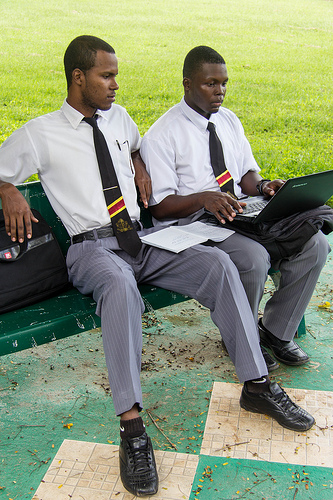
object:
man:
[139, 46, 329, 374]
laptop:
[204, 170, 333, 236]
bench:
[1, 180, 306, 358]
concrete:
[0, 232, 331, 499]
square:
[30, 437, 200, 499]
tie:
[81, 114, 144, 261]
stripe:
[106, 194, 127, 218]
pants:
[208, 227, 328, 343]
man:
[0, 35, 315, 499]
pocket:
[116, 143, 136, 179]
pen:
[114, 139, 122, 152]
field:
[0, 1, 332, 500]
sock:
[119, 417, 144, 438]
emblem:
[118, 426, 126, 432]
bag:
[0, 208, 66, 315]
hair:
[183, 45, 225, 76]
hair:
[63, 35, 116, 88]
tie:
[207, 122, 238, 200]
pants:
[64, 221, 269, 418]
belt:
[67, 218, 153, 248]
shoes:
[239, 379, 314, 432]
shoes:
[118, 434, 159, 497]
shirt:
[139, 100, 260, 226]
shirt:
[0, 100, 142, 232]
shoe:
[220, 338, 281, 371]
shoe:
[256, 316, 311, 367]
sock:
[243, 375, 272, 394]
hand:
[202, 190, 248, 226]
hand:
[0, 186, 39, 244]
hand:
[259, 177, 287, 197]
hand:
[133, 164, 153, 209]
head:
[182, 45, 228, 115]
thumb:
[29, 210, 41, 223]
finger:
[212, 194, 248, 225]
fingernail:
[219, 218, 226, 226]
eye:
[205, 80, 215, 85]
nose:
[109, 79, 119, 91]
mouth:
[211, 98, 224, 107]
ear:
[72, 68, 83, 86]